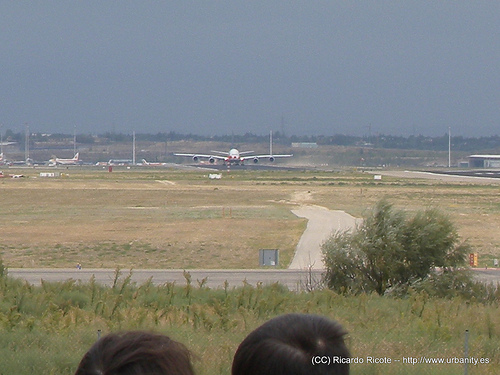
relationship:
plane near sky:
[174, 142, 286, 173] [1, 0, 483, 134]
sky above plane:
[1, 0, 483, 134] [174, 142, 286, 173]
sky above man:
[1, 0, 483, 134] [76, 329, 191, 375]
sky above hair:
[1, 0, 483, 134] [238, 306, 347, 374]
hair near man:
[238, 306, 347, 374] [76, 329, 191, 375]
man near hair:
[76, 329, 191, 375] [238, 306, 347, 374]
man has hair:
[76, 333, 148, 372] [75, 329, 196, 365]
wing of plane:
[173, 143, 225, 167] [168, 118, 298, 171]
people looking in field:
[227, 311, 357, 375] [0, 162, 485, 268]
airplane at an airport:
[44, 151, 84, 166] [0, 150, 484, 186]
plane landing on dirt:
[174, 142, 286, 166] [194, 162, 288, 172]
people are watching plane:
[66, 308, 358, 372] [174, 142, 286, 166]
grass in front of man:
[105, 256, 391, 338] [76, 329, 191, 375]